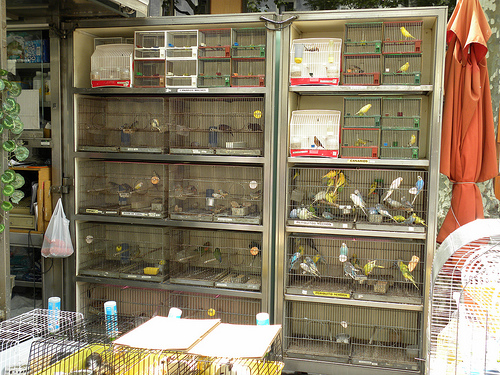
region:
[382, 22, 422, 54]
yellow bird in red cage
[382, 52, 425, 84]
yellow bird in green cage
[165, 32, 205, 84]
white empty bird cage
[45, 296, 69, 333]
water bottle on side of cage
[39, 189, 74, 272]
white bag with supplies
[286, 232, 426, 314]
several bids in a cage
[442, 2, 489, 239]
big orange umbrella closed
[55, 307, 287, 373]
cage with yellow bottom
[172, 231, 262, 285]
2 green birds in a cage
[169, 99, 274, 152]
2 brown birds in a cage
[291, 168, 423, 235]
cage filled with birds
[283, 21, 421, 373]
cages of birds stacked on shelves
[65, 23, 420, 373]
two shelving units filled with bird cages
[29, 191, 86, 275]
white plastic bag hanging from a hook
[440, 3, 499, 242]
burnt orange fabric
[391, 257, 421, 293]
green bird with a long tail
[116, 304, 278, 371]
two manila folders sitting on top of cages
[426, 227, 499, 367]
large white cage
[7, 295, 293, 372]
row of cages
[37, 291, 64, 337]
blue water bottle attached to a cage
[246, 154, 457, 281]
the box is full of birds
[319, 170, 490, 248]
the box is full of birds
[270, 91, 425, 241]
the box is full of birds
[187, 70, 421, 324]
the box is full of birds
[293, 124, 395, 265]
the box is full of birds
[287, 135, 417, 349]
the box is full of birds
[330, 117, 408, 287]
the box is full of birds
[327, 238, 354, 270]
blue and white parakeet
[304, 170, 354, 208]
three yellow and green rarakeets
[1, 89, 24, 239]
fake line of greenery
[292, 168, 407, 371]
three cages of birds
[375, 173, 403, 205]
a pure white parakeet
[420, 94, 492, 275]
a tied back orange curtain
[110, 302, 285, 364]
two stacks of paper on cages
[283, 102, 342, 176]
a bird in white cage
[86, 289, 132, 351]
blue and white feeding containers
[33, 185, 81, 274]
white grocery bag hanging on hhok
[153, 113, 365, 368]
the birds are caged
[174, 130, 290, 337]
the birds are caged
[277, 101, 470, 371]
the birds are caged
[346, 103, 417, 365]
the birds are caged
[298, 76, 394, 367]
the birds are caged